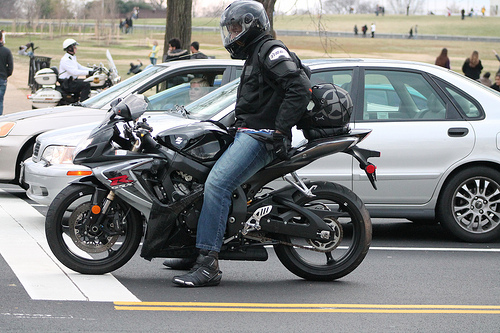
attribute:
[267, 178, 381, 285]
tire — Rear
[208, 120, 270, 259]
jeans — blue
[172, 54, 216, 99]
woman — sitting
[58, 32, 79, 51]
helmet — white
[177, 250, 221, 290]
sneakers — gray , couple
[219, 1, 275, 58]
helmet — black, clear 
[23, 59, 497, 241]
car — grey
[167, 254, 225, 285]
shoes — black 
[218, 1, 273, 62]
helmet — two gray, black motorcycle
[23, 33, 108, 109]
motorcycle — white 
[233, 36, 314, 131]
jacket — black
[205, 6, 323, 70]
helmet — white motorcycle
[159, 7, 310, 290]
man — black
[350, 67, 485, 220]
door — rear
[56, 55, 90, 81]
shirt. — white 